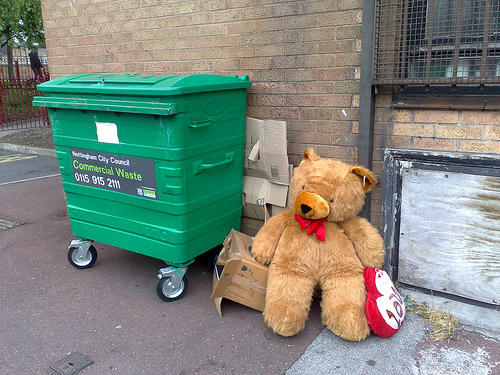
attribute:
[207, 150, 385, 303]
bear — brown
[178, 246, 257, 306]
box — brown, cardboard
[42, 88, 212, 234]
bin — large, green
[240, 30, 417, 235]
bricks — brown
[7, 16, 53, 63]
tree — green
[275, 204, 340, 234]
ribbon — red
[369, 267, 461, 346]
heart — red, white, stuffed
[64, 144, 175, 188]
sticker — black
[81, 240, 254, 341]
wheels — black, round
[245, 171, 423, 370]
bear — oversized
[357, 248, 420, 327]
decoration — valentine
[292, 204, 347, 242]
bow — red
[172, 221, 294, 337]
box — discarded, cardboard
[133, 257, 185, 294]
wheel — swiveling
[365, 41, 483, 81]
grate — metal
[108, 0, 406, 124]
wall — brick, beige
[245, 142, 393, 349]
teddy bear — brown, stuffed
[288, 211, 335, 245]
ribbon — red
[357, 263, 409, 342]
pillow — heart shaped, red, white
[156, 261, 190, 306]
wheel — silver, black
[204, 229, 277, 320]
box — cardboard, tan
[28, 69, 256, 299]
garbage can — large, green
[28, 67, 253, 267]
garbage — green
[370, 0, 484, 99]
wire — brown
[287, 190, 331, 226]
nose — orange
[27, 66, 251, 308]
can — green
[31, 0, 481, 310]
building — tan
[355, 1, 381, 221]
pole — gray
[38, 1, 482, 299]
wall — brick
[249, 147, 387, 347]
bear — large, stuffed, brown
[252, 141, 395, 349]
bear — stuffed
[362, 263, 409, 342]
heart — red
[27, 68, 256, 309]
trashcan — green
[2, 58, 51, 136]
fence — red